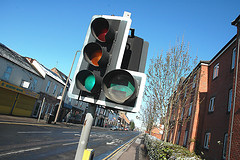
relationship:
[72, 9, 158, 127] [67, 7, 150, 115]
light on traffic signal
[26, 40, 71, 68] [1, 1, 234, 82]
clouds on sky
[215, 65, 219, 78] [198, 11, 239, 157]
window on building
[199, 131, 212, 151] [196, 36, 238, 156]
window on building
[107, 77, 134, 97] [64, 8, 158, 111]
arrow on signal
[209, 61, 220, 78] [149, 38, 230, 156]
window on building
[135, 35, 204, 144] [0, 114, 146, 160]
trees on block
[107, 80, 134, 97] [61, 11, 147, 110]
arrow on traffic light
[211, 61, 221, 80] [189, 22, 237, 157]
window in building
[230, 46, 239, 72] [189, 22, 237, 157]
window in building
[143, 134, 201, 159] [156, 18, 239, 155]
bushes near building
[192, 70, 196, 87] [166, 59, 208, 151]
window on building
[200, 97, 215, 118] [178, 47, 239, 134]
window on building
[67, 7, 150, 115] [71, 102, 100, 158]
traffic signal on pole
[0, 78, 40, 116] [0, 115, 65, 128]
building on pavement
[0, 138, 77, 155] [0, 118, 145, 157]
lines on street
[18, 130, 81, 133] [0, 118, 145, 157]
lines on street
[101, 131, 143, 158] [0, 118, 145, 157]
lines on street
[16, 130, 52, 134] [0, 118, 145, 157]
lines on street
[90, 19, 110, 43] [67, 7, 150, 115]
light on traffic signal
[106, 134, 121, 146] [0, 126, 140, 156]
arrow in street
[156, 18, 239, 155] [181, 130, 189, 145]
building has window